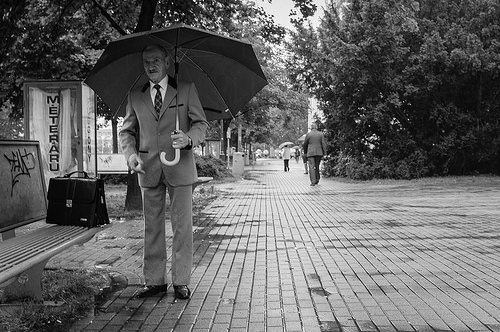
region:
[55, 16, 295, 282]
a man with umbrella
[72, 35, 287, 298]
a man with umbrella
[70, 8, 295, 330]
a man with umbrella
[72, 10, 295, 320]
a man with umbrella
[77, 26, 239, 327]
a man with umbrella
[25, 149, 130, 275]
a bag on the bench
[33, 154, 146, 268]
a bag on the bench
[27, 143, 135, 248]
a bag on the bench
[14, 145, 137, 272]
a bag on the bench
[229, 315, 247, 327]
brick laid to walk on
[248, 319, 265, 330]
brick laid to walk on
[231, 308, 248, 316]
brick laid to walk on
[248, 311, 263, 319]
brick laid to walk on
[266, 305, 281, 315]
brick laid to walk on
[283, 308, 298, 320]
brick laid to walk on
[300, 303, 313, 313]
brick laid to walk on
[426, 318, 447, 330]
brick laid to walk on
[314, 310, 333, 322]
brick laid to walk on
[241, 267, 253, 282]
brick laid to walk on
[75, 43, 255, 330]
A man in grey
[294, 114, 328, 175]
A man in grey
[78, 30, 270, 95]
A small black umbrella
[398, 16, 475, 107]
A thick tree branch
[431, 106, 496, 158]
A thick tree branch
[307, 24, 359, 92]
A thick tree branch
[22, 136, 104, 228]
A black briefcase bag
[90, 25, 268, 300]
man holding an umbrella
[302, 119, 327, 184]
man walking down the walkway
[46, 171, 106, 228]
briefcase sitting on a bench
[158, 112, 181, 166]
white handle of the umbrella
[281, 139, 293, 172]
lady walking with an umbrella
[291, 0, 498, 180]
trees in the distance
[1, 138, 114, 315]
bench with a briefcase on it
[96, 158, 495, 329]
brick walkway people are walking on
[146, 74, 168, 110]
man wearing a dressed white shirt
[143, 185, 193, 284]
pants of man standing under an umbrella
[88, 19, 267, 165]
a large open umbrella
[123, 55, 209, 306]
a person is standing up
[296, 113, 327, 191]
a person walking on a sidewalk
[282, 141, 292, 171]
a person walking on a sidewalk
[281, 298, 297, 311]
wet brick in the sidewalk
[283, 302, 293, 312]
wet brick in the sidewalk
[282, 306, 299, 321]
wet brick in the sidewalk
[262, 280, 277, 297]
wet brick in the sidewalk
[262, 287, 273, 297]
wet brick in the sidewalk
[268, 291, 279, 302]
wet brick in the sidewalk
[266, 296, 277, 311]
wet brick in the sidewalk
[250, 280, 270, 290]
wet brick in the sidewalk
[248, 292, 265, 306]
wet brick in the sidewalk